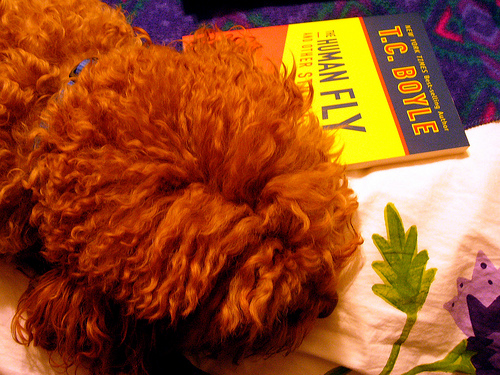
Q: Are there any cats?
A: No, there are no cats.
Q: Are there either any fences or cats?
A: No, there are no cats or fences.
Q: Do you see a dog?
A: Yes, there is a dog.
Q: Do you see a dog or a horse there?
A: Yes, there is a dog.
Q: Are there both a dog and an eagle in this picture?
A: No, there is a dog but no eagles.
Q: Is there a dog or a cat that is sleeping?
A: Yes, the dog is sleeping.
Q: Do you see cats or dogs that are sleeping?
A: Yes, the dog is sleeping.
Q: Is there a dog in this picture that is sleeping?
A: Yes, there is a dog that is sleeping.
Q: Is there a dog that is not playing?
A: Yes, there is a dog that is sleeping.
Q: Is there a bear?
A: No, there are no bears.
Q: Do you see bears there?
A: No, there are no bears.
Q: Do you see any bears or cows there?
A: No, there are no bears or cows.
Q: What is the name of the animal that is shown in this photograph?
A: The animal is a dog.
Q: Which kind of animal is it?
A: The animal is a dog.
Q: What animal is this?
A: This is a dog.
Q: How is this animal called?
A: This is a dog.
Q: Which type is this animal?
A: This is a dog.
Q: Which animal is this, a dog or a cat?
A: This is a dog.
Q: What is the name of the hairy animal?
A: The animal is a dog.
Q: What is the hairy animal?
A: The animal is a dog.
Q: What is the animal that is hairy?
A: The animal is a dog.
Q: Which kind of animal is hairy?
A: The animal is a dog.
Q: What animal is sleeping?
A: The animal is a dog.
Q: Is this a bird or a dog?
A: This is a dog.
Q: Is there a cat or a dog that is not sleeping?
A: No, there is a dog but it is sleeping.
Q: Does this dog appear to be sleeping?
A: Yes, the dog is sleeping.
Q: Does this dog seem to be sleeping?
A: Yes, the dog is sleeping.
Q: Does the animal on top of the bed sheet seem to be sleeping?
A: Yes, the dog is sleeping.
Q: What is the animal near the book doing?
A: The dog is sleeping.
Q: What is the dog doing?
A: The dog is sleeping.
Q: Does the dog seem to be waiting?
A: No, the dog is sleeping.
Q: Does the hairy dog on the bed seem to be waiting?
A: No, the dog is sleeping.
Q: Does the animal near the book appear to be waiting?
A: No, the dog is sleeping.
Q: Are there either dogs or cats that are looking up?
A: No, there is a dog but it is sleeping.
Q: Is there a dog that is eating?
A: No, there is a dog but it is sleeping.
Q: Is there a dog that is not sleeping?
A: No, there is a dog but it is sleeping.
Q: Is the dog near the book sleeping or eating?
A: The dog is sleeping.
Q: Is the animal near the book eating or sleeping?
A: The dog is sleeping.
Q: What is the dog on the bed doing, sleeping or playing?
A: The dog is sleeping.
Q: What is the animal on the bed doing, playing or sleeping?
A: The dog is sleeping.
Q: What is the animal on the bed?
A: The animal is a dog.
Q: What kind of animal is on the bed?
A: The animal is a dog.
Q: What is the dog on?
A: The dog is on the bed.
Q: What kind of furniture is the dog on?
A: The dog is on the bed.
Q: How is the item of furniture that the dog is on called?
A: The piece of furniture is a bed.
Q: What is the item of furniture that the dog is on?
A: The piece of furniture is a bed.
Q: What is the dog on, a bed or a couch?
A: The dog is on a bed.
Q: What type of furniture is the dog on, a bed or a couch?
A: The dog is on a bed.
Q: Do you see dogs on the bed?
A: Yes, there is a dog on the bed.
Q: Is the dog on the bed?
A: Yes, the dog is on the bed.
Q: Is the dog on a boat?
A: No, the dog is on the bed.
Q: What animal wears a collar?
A: The dog wears a collar.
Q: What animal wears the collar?
A: The dog wears a collar.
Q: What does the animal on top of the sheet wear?
A: The dog wears a collar.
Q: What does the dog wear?
A: The dog wears a collar.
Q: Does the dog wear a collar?
A: Yes, the dog wears a collar.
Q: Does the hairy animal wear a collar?
A: Yes, the dog wears a collar.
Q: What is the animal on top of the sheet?
A: The animal is a dog.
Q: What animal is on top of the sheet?
A: The animal is a dog.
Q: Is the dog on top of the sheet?
A: Yes, the dog is on top of the sheet.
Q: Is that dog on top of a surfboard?
A: No, the dog is on top of the sheet.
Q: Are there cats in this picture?
A: No, there are no cats.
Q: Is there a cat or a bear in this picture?
A: No, there are no cats or bears.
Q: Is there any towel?
A: No, there are no towels.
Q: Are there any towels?
A: No, there are no towels.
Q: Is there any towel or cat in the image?
A: No, there are no towels or cats.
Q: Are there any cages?
A: No, there are no cages.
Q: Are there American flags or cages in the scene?
A: No, there are no cages or American flags.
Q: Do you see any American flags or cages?
A: No, there are no cages or American flags.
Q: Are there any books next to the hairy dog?
A: Yes, there is a book next to the dog.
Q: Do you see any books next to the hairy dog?
A: Yes, there is a book next to the dog.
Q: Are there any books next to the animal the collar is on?
A: Yes, there is a book next to the dog.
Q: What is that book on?
A: The book is on the bed.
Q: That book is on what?
A: The book is on the bed.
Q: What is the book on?
A: The book is on the bed.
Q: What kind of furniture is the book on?
A: The book is on the bed.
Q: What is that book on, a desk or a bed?
A: The book is on a bed.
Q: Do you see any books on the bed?
A: Yes, there is a book on the bed.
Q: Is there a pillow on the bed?
A: No, there is a book on the bed.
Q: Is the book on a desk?
A: No, the book is on a bed.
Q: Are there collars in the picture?
A: Yes, there is a collar.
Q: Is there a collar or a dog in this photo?
A: Yes, there is a collar.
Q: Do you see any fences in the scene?
A: No, there are no fences.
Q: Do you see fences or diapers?
A: No, there are no fences or diapers.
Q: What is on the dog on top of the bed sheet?
A: The collar is on the dog.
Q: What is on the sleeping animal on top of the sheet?
A: The collar is on the dog.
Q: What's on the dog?
A: The collar is on the dog.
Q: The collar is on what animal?
A: The collar is on the dog.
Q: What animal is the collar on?
A: The collar is on the dog.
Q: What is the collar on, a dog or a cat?
A: The collar is on a dog.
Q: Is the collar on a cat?
A: No, the collar is on a dog.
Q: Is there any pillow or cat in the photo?
A: No, there are no cats or pillows.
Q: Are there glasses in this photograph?
A: No, there are no glasses.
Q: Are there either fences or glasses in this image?
A: No, there are no glasses or fences.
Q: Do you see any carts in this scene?
A: No, there are no carts.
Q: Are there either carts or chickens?
A: No, there are no carts or chickens.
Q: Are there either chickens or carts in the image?
A: No, there are no carts or chickens.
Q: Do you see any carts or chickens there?
A: No, there are no carts or chickens.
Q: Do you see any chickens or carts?
A: No, there are no carts or chickens.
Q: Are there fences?
A: No, there are no fences.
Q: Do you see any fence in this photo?
A: No, there are no fences.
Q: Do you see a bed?
A: Yes, there is a bed.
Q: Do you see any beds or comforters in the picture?
A: Yes, there is a bed.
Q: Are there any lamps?
A: No, there are no lamps.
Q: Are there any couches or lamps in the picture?
A: No, there are no lamps or couches.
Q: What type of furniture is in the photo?
A: The furniture is a bed.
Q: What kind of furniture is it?
A: The piece of furniture is a bed.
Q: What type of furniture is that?
A: This is a bed.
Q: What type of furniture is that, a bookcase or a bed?
A: This is a bed.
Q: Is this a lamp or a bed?
A: This is a bed.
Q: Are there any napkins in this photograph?
A: No, there are no napkins.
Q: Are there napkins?
A: No, there are no napkins.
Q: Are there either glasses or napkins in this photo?
A: No, there are no napkins or glasses.